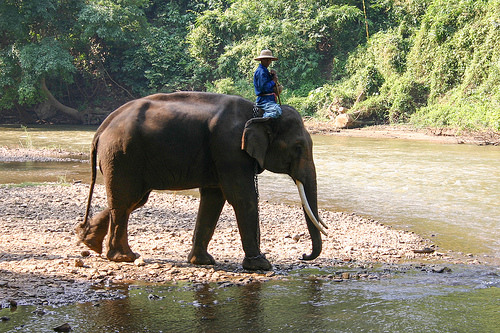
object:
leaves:
[0, 0, 499, 132]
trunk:
[292, 171, 322, 260]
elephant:
[76, 90, 327, 270]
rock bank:
[0, 182, 440, 309]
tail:
[80, 142, 97, 228]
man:
[253, 49, 283, 118]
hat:
[254, 50, 279, 61]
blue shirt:
[253, 63, 277, 105]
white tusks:
[295, 180, 329, 237]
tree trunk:
[336, 107, 369, 128]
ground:
[303, 120, 500, 145]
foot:
[74, 216, 108, 255]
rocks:
[335, 221, 410, 265]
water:
[1, 125, 498, 329]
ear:
[241, 117, 270, 169]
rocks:
[239, 278, 253, 283]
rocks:
[333, 279, 343, 282]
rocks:
[74, 258, 85, 267]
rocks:
[81, 251, 91, 257]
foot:
[106, 249, 136, 261]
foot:
[187, 252, 215, 265]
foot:
[242, 257, 272, 270]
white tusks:
[318, 215, 329, 229]